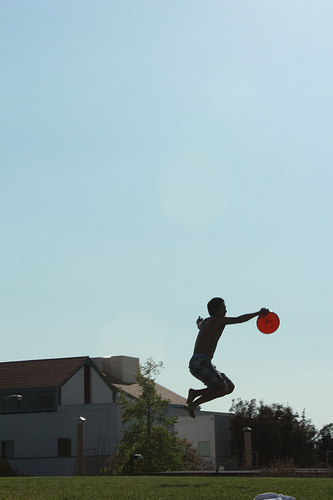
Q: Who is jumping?
A: The man.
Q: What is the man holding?
A: A frisbee.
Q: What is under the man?
A: Grass.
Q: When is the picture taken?
A: Daytime.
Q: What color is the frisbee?
A: Red.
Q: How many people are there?
A: One.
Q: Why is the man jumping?
A: To catch the frisbee.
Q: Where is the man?
A: In a park.